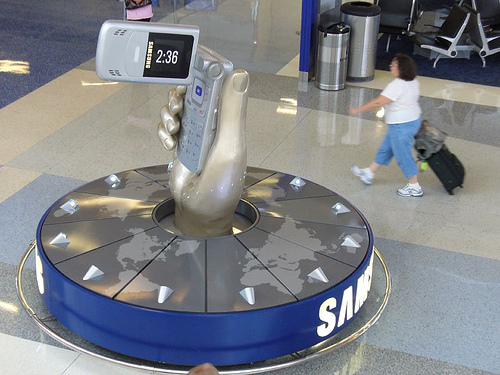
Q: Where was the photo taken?
A: It was taken at the display.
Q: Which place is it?
A: It is a display.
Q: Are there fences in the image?
A: No, there are no fences.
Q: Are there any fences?
A: No, there are no fences.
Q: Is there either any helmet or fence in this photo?
A: No, there are no fences or helmets.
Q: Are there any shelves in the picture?
A: No, there are no shelves.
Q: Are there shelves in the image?
A: No, there are no shelves.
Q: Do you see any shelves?
A: No, there are no shelves.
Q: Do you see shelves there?
A: No, there are no shelves.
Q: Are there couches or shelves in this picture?
A: No, there are no shelves or couches.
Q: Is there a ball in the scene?
A: No, there are no balls.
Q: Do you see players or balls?
A: No, there are no balls or players.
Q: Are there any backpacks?
A: Yes, there is a backpack.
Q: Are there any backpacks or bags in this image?
A: Yes, there is a backpack.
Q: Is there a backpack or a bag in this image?
A: Yes, there is a backpack.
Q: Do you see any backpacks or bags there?
A: Yes, there is a backpack.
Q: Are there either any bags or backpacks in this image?
A: Yes, there is a backpack.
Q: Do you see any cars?
A: No, there are no cars.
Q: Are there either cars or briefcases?
A: No, there are no cars or briefcases.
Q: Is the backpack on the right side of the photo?
A: Yes, the backpack is on the right of the image.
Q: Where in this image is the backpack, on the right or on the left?
A: The backpack is on the right of the image.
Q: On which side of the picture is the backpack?
A: The backpack is on the right of the image.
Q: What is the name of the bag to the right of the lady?
A: The bag is a backpack.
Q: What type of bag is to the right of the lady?
A: The bag is a backpack.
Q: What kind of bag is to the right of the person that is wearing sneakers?
A: The bag is a backpack.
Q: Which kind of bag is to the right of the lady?
A: The bag is a backpack.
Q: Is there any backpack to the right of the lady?
A: Yes, there is a backpack to the right of the lady.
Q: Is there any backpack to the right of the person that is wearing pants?
A: Yes, there is a backpack to the right of the lady.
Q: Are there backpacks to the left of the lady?
A: No, the backpack is to the right of the lady.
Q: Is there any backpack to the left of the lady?
A: No, the backpack is to the right of the lady.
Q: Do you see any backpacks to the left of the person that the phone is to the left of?
A: No, the backpack is to the right of the lady.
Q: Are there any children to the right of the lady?
A: No, there is a backpack to the right of the lady.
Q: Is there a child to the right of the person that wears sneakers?
A: No, there is a backpack to the right of the lady.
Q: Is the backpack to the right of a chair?
A: No, the backpack is to the right of the lady.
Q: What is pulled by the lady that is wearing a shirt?
A: The backpack is pulled by the lady.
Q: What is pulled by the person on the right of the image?
A: The backpack is pulled by the lady.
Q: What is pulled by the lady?
A: The backpack is pulled by the lady.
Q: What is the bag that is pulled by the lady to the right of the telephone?
A: The bag is a backpack.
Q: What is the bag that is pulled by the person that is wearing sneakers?
A: The bag is a backpack.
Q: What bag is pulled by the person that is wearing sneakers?
A: The bag is a backpack.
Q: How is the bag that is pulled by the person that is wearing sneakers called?
A: The bag is a backpack.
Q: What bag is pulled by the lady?
A: The bag is a backpack.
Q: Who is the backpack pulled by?
A: The backpack is pulled by the lady.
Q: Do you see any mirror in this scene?
A: No, there are no mirrors.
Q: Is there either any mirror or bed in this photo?
A: No, there are no mirrors or beds.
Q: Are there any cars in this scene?
A: No, there are no cars.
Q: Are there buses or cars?
A: No, there are no cars or buses.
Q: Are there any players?
A: No, there are no players.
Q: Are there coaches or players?
A: No, there are no players or coaches.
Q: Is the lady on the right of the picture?
A: Yes, the lady is on the right of the image.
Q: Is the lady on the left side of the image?
A: No, the lady is on the right of the image.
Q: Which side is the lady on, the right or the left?
A: The lady is on the right of the image.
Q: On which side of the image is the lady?
A: The lady is on the right of the image.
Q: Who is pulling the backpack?
A: The lady is pulling the backpack.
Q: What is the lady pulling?
A: The lady is pulling the backpack.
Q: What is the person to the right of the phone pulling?
A: The lady is pulling the backpack.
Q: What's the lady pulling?
A: The lady is pulling the backpack.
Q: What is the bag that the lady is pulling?
A: The bag is a backpack.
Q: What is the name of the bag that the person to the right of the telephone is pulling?
A: The bag is a backpack.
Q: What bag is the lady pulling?
A: The lady is pulling the backpack.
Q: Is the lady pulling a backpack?
A: Yes, the lady is pulling a backpack.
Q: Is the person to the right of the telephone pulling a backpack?
A: Yes, the lady is pulling a backpack.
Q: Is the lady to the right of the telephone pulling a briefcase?
A: No, the lady is pulling a backpack.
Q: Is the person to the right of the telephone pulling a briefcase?
A: No, the lady is pulling a backpack.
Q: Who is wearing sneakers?
A: The lady is wearing sneakers.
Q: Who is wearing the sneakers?
A: The lady is wearing sneakers.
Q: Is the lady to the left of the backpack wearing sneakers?
A: Yes, the lady is wearing sneakers.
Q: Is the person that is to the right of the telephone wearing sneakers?
A: Yes, the lady is wearing sneakers.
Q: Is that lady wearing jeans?
A: No, the lady is wearing sneakers.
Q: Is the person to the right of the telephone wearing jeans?
A: No, the lady is wearing sneakers.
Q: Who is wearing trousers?
A: The lady is wearing trousers.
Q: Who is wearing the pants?
A: The lady is wearing trousers.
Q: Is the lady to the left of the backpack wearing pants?
A: Yes, the lady is wearing pants.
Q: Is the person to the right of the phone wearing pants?
A: Yes, the lady is wearing pants.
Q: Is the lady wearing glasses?
A: No, the lady is wearing pants.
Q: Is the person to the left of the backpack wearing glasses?
A: No, the lady is wearing pants.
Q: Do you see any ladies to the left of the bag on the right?
A: Yes, there is a lady to the left of the backpack.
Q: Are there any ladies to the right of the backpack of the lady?
A: No, the lady is to the left of the backpack.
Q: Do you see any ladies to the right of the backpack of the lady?
A: No, the lady is to the left of the backpack.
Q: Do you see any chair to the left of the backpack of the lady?
A: No, there is a lady to the left of the backpack.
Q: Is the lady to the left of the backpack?
A: Yes, the lady is to the left of the backpack.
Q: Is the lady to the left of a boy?
A: No, the lady is to the left of the backpack.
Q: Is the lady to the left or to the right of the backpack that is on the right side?
A: The lady is to the left of the backpack.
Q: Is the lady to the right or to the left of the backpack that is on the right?
A: The lady is to the left of the backpack.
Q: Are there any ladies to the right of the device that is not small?
A: Yes, there is a lady to the right of the telephone.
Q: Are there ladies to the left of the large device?
A: No, the lady is to the right of the phone.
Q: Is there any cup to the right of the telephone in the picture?
A: No, there is a lady to the right of the telephone.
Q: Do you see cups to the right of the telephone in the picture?
A: No, there is a lady to the right of the telephone.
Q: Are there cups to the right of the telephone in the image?
A: No, there is a lady to the right of the telephone.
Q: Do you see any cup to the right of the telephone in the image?
A: No, there is a lady to the right of the telephone.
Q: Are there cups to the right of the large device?
A: No, there is a lady to the right of the telephone.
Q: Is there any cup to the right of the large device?
A: No, there is a lady to the right of the telephone.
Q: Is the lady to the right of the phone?
A: Yes, the lady is to the right of the phone.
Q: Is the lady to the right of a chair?
A: No, the lady is to the right of the phone.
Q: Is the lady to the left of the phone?
A: No, the lady is to the right of the phone.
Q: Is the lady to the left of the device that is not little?
A: No, the lady is to the right of the phone.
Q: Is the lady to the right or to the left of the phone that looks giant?
A: The lady is to the right of the telephone.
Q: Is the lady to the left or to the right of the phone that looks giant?
A: The lady is to the right of the telephone.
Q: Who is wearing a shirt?
A: The lady is wearing a shirt.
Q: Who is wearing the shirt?
A: The lady is wearing a shirt.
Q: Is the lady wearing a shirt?
A: Yes, the lady is wearing a shirt.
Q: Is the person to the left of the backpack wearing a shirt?
A: Yes, the lady is wearing a shirt.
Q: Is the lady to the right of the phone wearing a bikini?
A: No, the lady is wearing a shirt.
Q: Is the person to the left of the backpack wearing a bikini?
A: No, the lady is wearing a shirt.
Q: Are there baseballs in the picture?
A: No, there are no baseballs.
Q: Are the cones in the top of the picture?
A: No, the cones are in the bottom of the image.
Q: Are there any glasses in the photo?
A: No, there are no glasses.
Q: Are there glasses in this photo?
A: No, there are no glasses.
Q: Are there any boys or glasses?
A: No, there are no glasses or boys.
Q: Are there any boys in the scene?
A: No, there are no boys.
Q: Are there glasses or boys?
A: No, there are no boys or glasses.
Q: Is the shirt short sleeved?
A: Yes, the shirt is short sleeved.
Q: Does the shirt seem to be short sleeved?
A: Yes, the shirt is short sleeved.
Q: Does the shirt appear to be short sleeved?
A: Yes, the shirt is short sleeved.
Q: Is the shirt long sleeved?
A: No, the shirt is short sleeved.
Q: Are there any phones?
A: Yes, there is a phone.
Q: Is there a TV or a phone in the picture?
A: Yes, there is a phone.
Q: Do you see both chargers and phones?
A: No, there is a phone but no chargers.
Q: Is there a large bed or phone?
A: Yes, there is a large phone.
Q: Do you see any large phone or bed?
A: Yes, there is a large phone.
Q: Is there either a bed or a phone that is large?
A: Yes, the phone is large.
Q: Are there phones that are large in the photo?
A: Yes, there is a large phone.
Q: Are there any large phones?
A: Yes, there is a large phone.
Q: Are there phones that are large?
A: Yes, there is a phone that is large.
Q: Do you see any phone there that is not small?
A: Yes, there is a large phone.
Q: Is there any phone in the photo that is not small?
A: Yes, there is a large phone.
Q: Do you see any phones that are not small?
A: Yes, there is a large phone.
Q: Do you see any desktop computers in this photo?
A: No, there are no desktop computers.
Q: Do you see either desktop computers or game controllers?
A: No, there are no desktop computers or game controllers.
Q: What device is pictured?
A: The device is a phone.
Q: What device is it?
A: The device is a phone.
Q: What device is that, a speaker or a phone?
A: That is a phone.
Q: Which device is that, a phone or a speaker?
A: That is a phone.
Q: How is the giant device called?
A: The device is a phone.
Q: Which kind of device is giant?
A: The device is a phone.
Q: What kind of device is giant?
A: The device is a phone.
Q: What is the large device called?
A: The device is a phone.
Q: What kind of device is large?
A: The device is a phone.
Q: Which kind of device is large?
A: The device is a phone.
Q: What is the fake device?
A: The device is a phone.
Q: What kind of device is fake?
A: The device is a phone.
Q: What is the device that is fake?
A: The device is a phone.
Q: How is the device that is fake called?
A: The device is a phone.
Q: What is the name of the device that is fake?
A: The device is a phone.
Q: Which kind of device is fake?
A: The device is a phone.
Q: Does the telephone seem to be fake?
A: Yes, the telephone is fake.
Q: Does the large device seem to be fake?
A: Yes, the telephone is fake.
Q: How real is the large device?
A: The phone is fake.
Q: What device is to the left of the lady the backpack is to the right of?
A: The device is a phone.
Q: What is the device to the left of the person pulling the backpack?
A: The device is a phone.